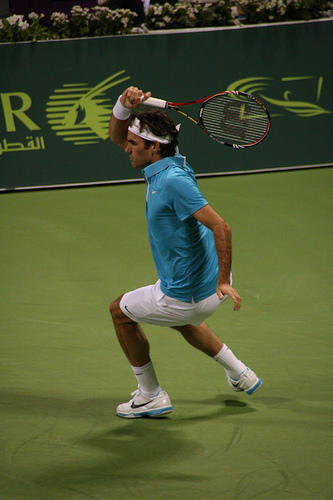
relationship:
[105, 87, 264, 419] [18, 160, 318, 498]
man on court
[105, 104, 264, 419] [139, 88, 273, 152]
man holding racquet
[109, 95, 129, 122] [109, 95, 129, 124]
band on wrist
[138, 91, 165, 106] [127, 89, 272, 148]
handle of tennis racquet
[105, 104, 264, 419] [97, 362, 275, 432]
man wearing nike shoes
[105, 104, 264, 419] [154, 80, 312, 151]
man holding racket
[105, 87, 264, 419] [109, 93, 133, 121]
man wearing a wristband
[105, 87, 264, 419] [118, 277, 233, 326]
man wearing shorts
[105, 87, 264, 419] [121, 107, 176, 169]
man has head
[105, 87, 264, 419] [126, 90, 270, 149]
man swinging racket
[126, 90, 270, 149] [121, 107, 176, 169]
racket over head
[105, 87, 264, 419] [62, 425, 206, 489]
man has shadow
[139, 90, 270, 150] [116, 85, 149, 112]
racket in hand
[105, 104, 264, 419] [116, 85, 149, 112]
man has hand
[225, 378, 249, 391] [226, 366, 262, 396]
nike sign on shoe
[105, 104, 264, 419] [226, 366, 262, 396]
man has shoe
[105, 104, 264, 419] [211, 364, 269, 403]
man has sneaker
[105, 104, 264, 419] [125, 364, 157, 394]
man has sock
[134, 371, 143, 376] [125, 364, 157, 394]
nike sign on sock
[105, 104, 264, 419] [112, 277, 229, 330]
man wearing shorts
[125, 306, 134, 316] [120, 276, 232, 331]
logo on shorts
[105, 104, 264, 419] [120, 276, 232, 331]
man has shorts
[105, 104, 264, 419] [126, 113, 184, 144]
man wearing headband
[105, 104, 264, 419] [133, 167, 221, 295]
man wearing shirt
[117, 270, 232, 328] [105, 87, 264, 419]
shorts on man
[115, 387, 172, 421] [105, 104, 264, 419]
nike shoes on man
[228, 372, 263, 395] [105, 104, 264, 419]
shoe on man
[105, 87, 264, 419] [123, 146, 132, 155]
man has nose